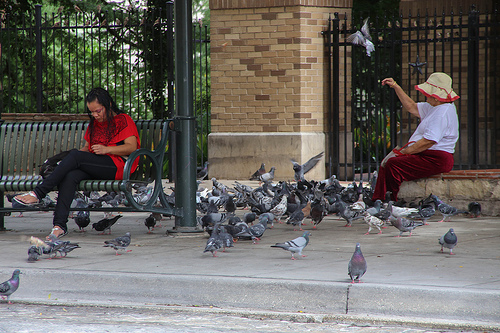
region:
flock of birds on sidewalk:
[1, 135, 484, 310]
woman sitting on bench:
[1, 86, 198, 241]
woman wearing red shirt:
[54, 106, 146, 177]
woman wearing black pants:
[27, 142, 132, 226]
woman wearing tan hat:
[409, 60, 461, 111]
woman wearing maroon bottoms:
[368, 132, 445, 203]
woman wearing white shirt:
[404, 84, 462, 154]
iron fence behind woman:
[3, 0, 485, 175]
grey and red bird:
[337, 243, 375, 283]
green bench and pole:
[2, 10, 217, 240]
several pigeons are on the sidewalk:
[11, 148, 464, 315]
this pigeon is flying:
[343, 13, 382, 55]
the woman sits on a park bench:
[13, 74, 144, 258]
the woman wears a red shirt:
[83, 109, 137, 184]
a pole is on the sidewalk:
[158, 4, 216, 254]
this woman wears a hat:
[411, 65, 462, 108]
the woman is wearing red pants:
[368, 138, 455, 207]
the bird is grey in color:
[266, 223, 328, 258]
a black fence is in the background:
[1, 18, 499, 178]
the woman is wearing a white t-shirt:
[402, 97, 463, 159]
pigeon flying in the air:
[343, 18, 377, 58]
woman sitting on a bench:
[7, 87, 140, 239]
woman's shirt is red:
[82, 115, 141, 172]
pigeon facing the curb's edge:
[342, 237, 368, 289]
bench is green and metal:
[1, 118, 41, 189]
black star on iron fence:
[402, 52, 427, 77]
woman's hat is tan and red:
[415, 71, 457, 103]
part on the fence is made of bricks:
[207, 2, 338, 137]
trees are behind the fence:
[15, 3, 205, 88]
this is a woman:
[365, 50, 487, 218]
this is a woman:
[0, 83, 149, 250]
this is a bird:
[322, 233, 399, 282]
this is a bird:
[421, 220, 483, 286]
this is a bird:
[264, 217, 332, 274]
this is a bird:
[99, 225, 150, 266]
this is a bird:
[25, 236, 57, 266]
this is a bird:
[192, 215, 252, 277]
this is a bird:
[230, 191, 284, 251]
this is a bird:
[297, 185, 334, 225]